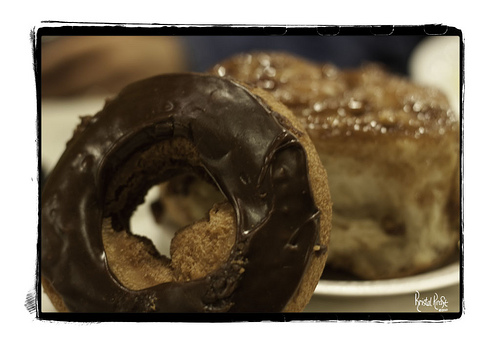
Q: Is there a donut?
A: Yes, there is a donut.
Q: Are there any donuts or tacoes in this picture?
A: Yes, there is a donut.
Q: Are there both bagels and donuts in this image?
A: No, there is a donut but no bagels.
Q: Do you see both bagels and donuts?
A: No, there is a donut but no bagels.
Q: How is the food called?
A: The food is a donut.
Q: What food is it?
A: The food is a donut.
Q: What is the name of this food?
A: This is a donut.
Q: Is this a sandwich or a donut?
A: This is a donut.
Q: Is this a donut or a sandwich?
A: This is a donut.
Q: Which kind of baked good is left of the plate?
A: The food is a donut.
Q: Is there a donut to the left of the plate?
A: Yes, there is a donut to the left of the plate.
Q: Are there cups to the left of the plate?
A: No, there is a donut to the left of the plate.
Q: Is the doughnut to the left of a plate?
A: Yes, the doughnut is to the left of a plate.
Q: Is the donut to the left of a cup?
A: No, the donut is to the left of a plate.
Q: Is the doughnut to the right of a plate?
A: No, the doughnut is to the left of a plate.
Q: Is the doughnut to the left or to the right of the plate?
A: The doughnut is to the left of the plate.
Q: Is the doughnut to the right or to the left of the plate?
A: The doughnut is to the left of the plate.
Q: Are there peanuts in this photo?
A: No, there are no peanuts.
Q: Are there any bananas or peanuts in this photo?
A: No, there are no peanuts or bananas.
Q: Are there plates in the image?
A: Yes, there is a plate.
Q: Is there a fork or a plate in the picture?
A: Yes, there is a plate.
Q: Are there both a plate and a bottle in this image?
A: No, there is a plate but no bottles.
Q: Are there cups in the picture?
A: No, there are no cups.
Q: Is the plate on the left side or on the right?
A: The plate is on the right of the image.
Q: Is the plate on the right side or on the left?
A: The plate is on the right of the image.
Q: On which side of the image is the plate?
A: The plate is on the right of the image.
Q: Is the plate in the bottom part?
A: Yes, the plate is in the bottom of the image.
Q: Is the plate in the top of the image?
A: No, the plate is in the bottom of the image.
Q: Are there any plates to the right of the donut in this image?
A: Yes, there is a plate to the right of the donut.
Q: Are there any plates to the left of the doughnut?
A: No, the plate is to the right of the doughnut.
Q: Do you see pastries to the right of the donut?
A: No, there is a plate to the right of the donut.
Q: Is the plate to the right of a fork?
A: No, the plate is to the right of a donut.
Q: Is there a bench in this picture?
A: No, there are no benches.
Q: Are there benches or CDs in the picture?
A: No, there are no benches or cds.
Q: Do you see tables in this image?
A: Yes, there is a table.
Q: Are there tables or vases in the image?
A: Yes, there is a table.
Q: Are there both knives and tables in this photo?
A: No, there is a table but no knives.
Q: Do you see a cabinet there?
A: No, there are no cabinets.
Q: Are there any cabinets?
A: No, there are no cabinets.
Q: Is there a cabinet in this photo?
A: No, there are no cabinets.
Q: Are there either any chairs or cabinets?
A: No, there are no cabinets or chairs.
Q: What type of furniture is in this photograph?
A: The furniture is a table.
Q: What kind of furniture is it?
A: The piece of furniture is a table.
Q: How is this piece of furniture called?
A: This is a table.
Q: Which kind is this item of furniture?
A: This is a table.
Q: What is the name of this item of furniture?
A: This is a table.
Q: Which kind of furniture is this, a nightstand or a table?
A: This is a table.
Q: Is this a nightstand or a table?
A: This is a table.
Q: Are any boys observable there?
A: No, there are no boys.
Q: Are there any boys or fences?
A: No, there are no boys or fences.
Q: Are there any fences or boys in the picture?
A: No, there are no boys or fences.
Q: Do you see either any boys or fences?
A: No, there are no boys or fences.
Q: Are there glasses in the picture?
A: No, there are no glasses.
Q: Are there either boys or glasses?
A: No, there are no glasses or boys.